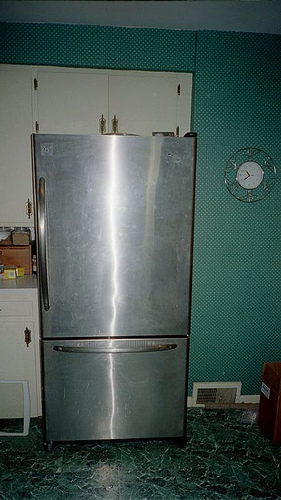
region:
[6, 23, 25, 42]
green and white Wall paper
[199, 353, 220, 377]
green and white Wall paper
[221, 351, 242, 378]
green and white Wall paper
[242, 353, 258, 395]
green and white Wall paper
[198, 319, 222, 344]
green and white Wall paper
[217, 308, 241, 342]
green and white Wall paper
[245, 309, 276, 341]
green and white Wall paper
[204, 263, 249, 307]
green and white Wall paper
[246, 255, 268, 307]
green and white Wall paper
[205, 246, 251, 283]
green and white Wall paper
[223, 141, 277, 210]
the clock is on the wall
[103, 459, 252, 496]
the floor is marble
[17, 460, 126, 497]
the floor is green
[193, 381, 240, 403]
the vent is white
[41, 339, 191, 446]
the freezer is silver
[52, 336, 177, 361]
the freezer has a handle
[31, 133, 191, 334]
the fridge is silver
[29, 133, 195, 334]
the fridge has a handle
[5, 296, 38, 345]
the cabinet is white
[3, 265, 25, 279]
the box is yellow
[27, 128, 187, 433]
the refrigerator door is silver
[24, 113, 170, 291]
the refrigerator door is silver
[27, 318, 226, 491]
the refrigerator door is closed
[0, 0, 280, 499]
kitchen area of a house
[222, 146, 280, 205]
circular wall clock mounted on wall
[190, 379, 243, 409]
air vent in the wall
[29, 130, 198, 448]
stainless steel refrigerator in kitchen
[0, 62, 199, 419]
white wooden kitchen cabinets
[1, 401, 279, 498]
teal colored tile on kitchen floor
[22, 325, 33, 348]
door handle on kitchen cabinet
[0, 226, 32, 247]
canister set on top of bread box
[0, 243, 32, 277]
wooden bread box on top of kitchen cabinet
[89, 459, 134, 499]
worn spot in kitchen tile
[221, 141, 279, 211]
a clock on a wall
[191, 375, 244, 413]
vents on the wall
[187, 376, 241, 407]
frame of vent is white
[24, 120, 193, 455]
a refrigerator color silver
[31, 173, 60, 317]
handle of a refrigerator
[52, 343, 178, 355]
handle of a refrigerator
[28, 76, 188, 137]
cabinet on top of refrigerator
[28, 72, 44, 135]
hinges of cabinet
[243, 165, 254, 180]
handles of clock are black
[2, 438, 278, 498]
floor of kitchen is green